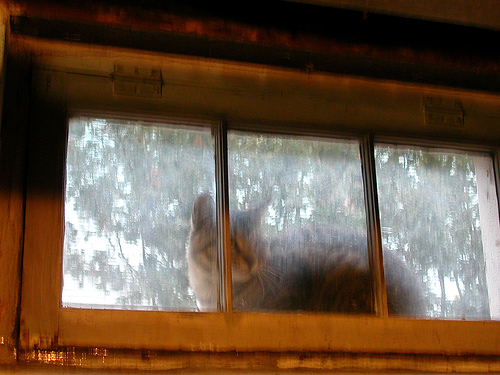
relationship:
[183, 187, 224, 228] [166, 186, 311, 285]
ears on cat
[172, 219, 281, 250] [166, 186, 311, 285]
eyes on cat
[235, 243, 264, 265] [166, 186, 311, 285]
nose on cat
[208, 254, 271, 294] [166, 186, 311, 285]
whiskers on cat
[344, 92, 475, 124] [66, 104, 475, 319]
hinge on windows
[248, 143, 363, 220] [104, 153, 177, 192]
tree has leaves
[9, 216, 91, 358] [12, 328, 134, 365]
wall has goop